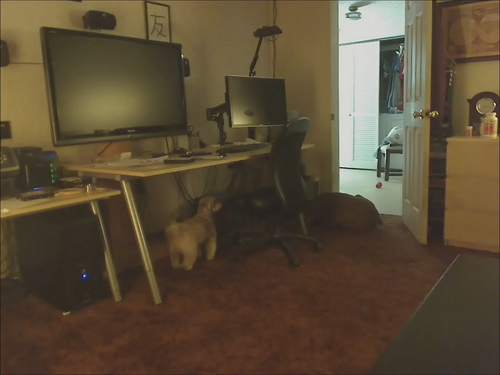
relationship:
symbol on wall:
[145, 1, 175, 41] [3, 1, 263, 272]